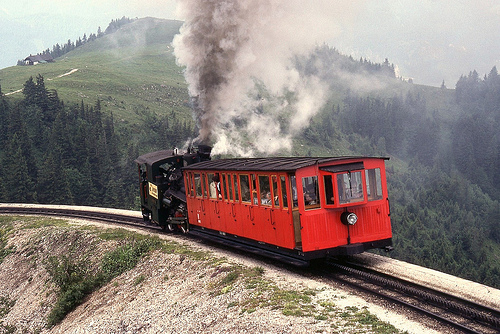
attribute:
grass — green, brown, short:
[0, 211, 407, 332]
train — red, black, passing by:
[133, 138, 394, 274]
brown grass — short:
[90, 242, 159, 283]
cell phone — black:
[130, 132, 214, 239]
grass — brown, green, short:
[81, 66, 169, 106]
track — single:
[0, 190, 499, 330]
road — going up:
[0, 14, 164, 118]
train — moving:
[137, 107, 409, 290]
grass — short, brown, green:
[69, 269, 287, 330]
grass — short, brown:
[133, 143, 399, 275]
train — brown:
[133, 145, 394, 265]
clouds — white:
[22, 20, 54, 37]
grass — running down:
[43, 235, 157, 320]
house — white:
[23, 53, 48, 68]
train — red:
[120, 137, 352, 247]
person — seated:
[304, 192, 314, 206]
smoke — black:
[194, 11, 226, 128]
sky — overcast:
[353, 51, 493, 182]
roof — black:
[177, 134, 410, 194]